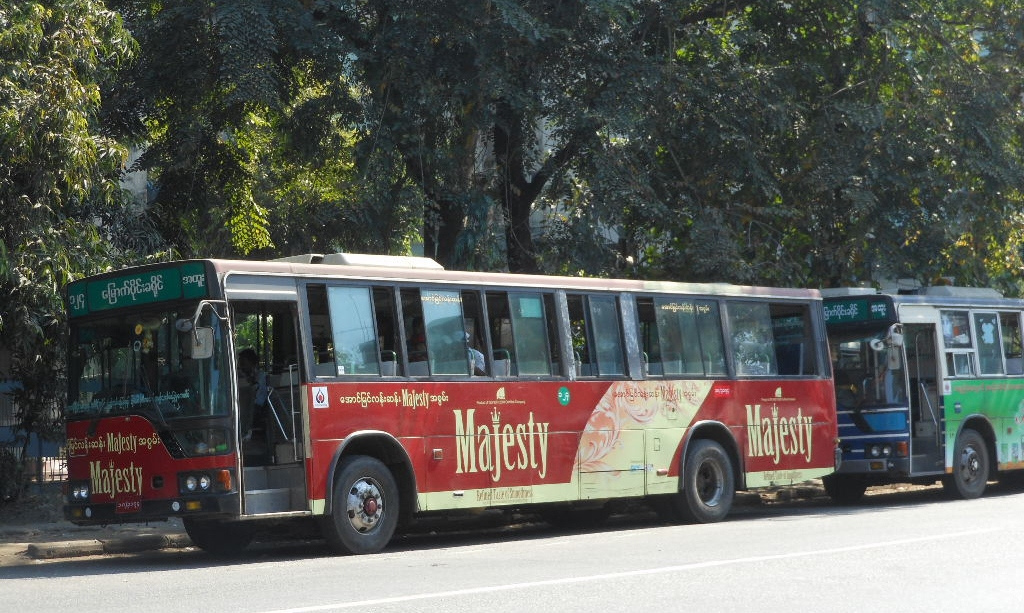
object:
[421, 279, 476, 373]
window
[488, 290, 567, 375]
window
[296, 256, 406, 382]
window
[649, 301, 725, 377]
window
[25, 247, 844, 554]
passenger bus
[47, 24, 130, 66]
leaves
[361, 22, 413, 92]
leaves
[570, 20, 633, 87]
leaves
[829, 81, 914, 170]
leaves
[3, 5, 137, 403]
trees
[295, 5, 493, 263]
trees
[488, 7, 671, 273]
trees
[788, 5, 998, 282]
trees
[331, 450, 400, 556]
tire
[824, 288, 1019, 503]
bus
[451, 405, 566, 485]
logo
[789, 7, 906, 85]
leaves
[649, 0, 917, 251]
tree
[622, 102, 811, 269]
tree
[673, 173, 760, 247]
leaves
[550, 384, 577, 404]
sticker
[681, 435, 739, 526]
tire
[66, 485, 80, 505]
headlight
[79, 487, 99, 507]
headlight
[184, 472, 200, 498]
headlight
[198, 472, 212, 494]
headlight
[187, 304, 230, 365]
mirror